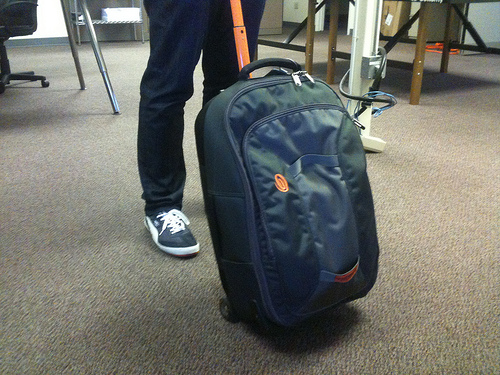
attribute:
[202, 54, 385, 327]
backpack — gray, light, blue, dark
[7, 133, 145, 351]
carpet — gray, grey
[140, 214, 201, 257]
shoe — blue, white, black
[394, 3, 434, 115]
legs — metal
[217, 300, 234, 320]
wheels — black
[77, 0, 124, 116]
legs — metal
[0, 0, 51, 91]
chair — black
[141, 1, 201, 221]
pants — black, navy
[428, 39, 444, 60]
cord — red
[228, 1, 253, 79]
handle — orange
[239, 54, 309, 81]
handle — black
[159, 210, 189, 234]
laces — white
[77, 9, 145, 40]
shelves — metal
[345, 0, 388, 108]
beam — white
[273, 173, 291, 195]
design — orange